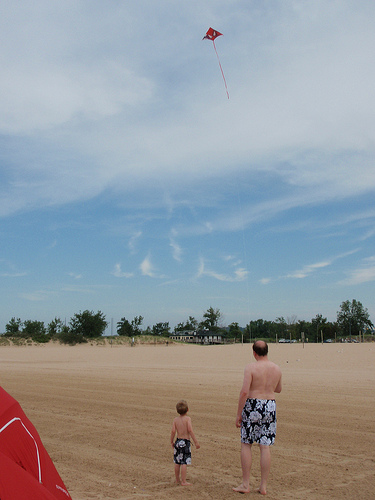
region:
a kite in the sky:
[190, 21, 258, 118]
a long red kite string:
[210, 40, 239, 103]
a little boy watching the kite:
[150, 387, 199, 489]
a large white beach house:
[175, 327, 222, 342]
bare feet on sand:
[231, 482, 274, 496]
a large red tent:
[0, 394, 63, 499]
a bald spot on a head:
[254, 340, 266, 348]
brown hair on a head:
[177, 400, 186, 410]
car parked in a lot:
[277, 332, 298, 344]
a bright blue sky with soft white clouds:
[22, 181, 357, 292]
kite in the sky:
[183, 24, 254, 102]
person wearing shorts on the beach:
[160, 397, 199, 490]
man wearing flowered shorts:
[224, 331, 290, 499]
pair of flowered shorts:
[231, 396, 282, 451]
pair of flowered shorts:
[170, 438, 194, 465]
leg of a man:
[227, 429, 257, 493]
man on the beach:
[222, 336, 291, 499]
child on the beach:
[158, 393, 204, 493]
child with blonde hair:
[161, 390, 202, 492]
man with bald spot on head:
[224, 331, 294, 498]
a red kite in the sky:
[195, 28, 241, 101]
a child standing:
[168, 399, 203, 484]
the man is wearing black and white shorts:
[242, 399, 278, 444]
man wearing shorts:
[241, 396, 276, 442]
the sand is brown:
[53, 352, 146, 418]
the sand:
[84, 358, 162, 433]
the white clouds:
[119, 260, 230, 283]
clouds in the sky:
[117, 259, 248, 281]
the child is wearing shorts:
[175, 440, 193, 466]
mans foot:
[231, 481, 249, 492]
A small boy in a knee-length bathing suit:
[153, 393, 214, 497]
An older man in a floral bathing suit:
[230, 336, 283, 498]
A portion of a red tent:
[2, 386, 51, 499]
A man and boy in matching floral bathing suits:
[147, 326, 285, 498]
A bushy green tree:
[71, 306, 104, 339]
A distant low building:
[166, 327, 220, 345]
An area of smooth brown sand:
[48, 373, 151, 448]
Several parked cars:
[278, 336, 361, 343]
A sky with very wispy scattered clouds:
[141, 250, 307, 301]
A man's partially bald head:
[246, 338, 278, 362]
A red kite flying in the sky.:
[201, 24, 231, 101]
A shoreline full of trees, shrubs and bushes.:
[1, 299, 373, 348]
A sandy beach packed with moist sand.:
[22, 357, 238, 391]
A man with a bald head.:
[252, 340, 269, 359]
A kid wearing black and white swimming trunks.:
[167, 399, 200, 485]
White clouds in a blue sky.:
[35, 27, 188, 178]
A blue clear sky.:
[18, 222, 84, 303]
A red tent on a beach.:
[0, 385, 72, 499]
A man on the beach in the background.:
[164, 337, 169, 346]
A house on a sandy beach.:
[169, 333, 225, 348]